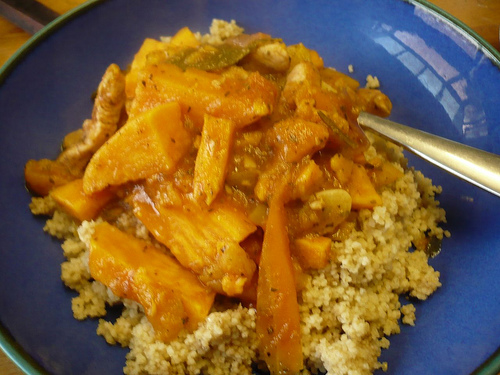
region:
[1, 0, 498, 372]
the plate is blue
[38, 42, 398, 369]
orange vegetable on the plate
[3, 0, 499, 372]
a plate of couscous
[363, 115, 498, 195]
the spoon is silver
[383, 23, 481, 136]
a reflection on the plate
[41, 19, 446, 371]
the food is seasoned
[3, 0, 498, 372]
a lot of food on a plate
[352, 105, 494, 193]
a spoon on a dish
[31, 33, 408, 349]
Cooked sweet potatoes on a plate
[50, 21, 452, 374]
Sweet potatoes on top of a beige grain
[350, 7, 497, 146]
Reflection of window on plate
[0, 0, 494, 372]
Blue dinner plate with green trim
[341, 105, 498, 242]
Silver utensil on blue plate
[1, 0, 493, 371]
Blue dinner plate on a wooden table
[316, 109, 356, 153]
Strip of pepper on sweet potato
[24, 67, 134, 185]
Ginger root next to cooked sweet potatoes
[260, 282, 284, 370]
Brown seasoning on piece of sweet potato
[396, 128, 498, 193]
Reflection of light on silver utensil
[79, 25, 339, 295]
orange meat on plate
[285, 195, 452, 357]
white couscous on plate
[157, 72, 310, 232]
chicken in orange sauce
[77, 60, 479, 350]
meal on blue plate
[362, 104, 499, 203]
silver utensil on plate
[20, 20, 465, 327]
plate on brown table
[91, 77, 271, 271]
white meat in sauce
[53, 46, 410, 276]
white meat with vegetables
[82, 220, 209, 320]
a piece of sauce covered chicken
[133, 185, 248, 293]
a piece of sauce covered chicken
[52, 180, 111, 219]
a piece of sauce covered chicken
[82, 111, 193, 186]
a piece of sauce covered chicken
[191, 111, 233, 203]
a piece of sauce covered chicken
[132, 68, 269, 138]
a piece of sauce covered chicken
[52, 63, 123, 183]
a piece of sauce covered chicken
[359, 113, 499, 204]
the handle of a utensil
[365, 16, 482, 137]
a reflection on the plate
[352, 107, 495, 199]
Handle of metal utensil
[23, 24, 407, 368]
Orange vegetable dish on plate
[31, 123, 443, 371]
cous cous on blue plate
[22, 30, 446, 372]
Vegetable and cous cous dish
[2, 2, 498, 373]
Round blue plate on table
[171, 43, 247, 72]
Green vegetable in dish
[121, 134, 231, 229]
Light reflection of glaze on dish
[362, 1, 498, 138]
Sunshine reflected in blue plate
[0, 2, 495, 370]
Aqua colored trim on plate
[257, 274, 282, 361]
Black flecks of spices on dish